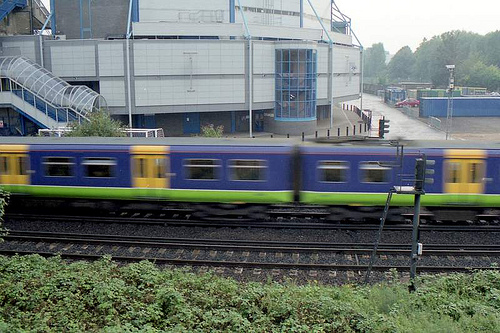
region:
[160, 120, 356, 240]
the train is blue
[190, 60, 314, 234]
the train is blue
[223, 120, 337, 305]
the train is blue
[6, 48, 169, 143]
covered staircase next to a building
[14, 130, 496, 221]
blue and yellow train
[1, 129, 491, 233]
training moving on a the tracks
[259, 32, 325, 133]
window with blue frames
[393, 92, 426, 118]
small, parked red car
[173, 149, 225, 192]
rectangular train window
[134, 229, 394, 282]
train tracks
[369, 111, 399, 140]
black stoplight near train tracks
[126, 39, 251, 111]
white exterior wall of a building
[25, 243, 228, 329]
green shrub near a train track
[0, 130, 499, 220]
The train is moving.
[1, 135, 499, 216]
Train is blue, yellow and green.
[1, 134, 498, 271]
Train is on a track.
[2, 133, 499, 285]
Gravel between the tracks.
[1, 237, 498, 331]
Vegetation alongside the tracks.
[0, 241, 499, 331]
The vegetation is green.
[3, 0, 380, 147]
Covered stairway on building.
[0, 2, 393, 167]
Building is blue and white.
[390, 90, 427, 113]
The car is red.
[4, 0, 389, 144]
Building has gray trim.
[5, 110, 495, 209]
a train in motion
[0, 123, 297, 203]
the train is blue and yellow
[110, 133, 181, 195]
the doors of the train are yellow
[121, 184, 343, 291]
there are 2 train tracks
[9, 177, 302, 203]
a green border on the bottom of the train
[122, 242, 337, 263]
gravel in between the tracks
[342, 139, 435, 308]
a traffic signal post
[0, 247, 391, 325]
shrubs on the side of the track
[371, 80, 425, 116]
a red car parked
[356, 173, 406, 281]
a ladder on the traffic light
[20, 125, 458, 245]
A train riding on the tracks.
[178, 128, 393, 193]
The train has windows.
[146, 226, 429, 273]
The tracks have gravel between them.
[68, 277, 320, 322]
The bushes are on the side of the track.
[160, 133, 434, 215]
The train is yellow blue and green.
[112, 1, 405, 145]
The train station on the other side of the tracks.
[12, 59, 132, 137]
Staircase connected to the station.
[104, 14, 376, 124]
The building is white.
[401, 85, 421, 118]
A red car parked in front of the building.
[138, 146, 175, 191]
The door of the train is yellow.